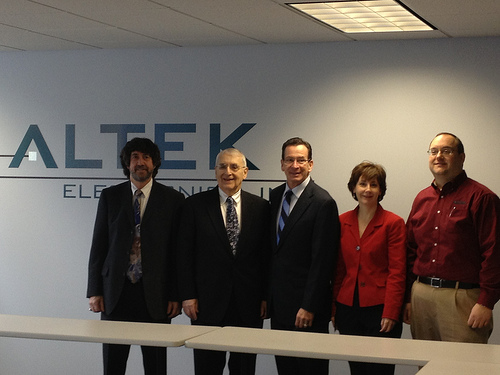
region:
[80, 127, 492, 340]
group of people posing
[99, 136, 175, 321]
man with a beard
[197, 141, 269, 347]
older man wearing glasses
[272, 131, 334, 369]
man wearing blue striped tie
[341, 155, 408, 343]
woman in red jacket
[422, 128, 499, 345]
man in burgundy shirt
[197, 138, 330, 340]
two men wearing glasses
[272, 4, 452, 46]
ceiling light panel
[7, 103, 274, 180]
word altek in blue letters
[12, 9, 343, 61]
panel pieces of ceiling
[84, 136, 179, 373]
man wearing suit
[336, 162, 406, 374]
woman wearing red jacket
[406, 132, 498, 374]
man wearing red shirt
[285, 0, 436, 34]
flourescent light on ceiling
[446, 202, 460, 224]
pen in shirt pocket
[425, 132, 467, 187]
man wearing glasses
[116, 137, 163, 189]
man with a beard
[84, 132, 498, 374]
five people standing in a room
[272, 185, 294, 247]
blue striped tie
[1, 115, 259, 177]
company logo on back of wall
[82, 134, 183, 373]
The man is standing.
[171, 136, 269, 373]
The man is standing.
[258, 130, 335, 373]
The man is standing.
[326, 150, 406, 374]
The woman is standing.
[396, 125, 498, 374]
The man is standing.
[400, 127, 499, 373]
The man is smiling.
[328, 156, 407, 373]
The woman is smiling.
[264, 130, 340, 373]
The man is smiling.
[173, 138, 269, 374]
The man is smiling.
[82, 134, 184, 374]
The man is smiling.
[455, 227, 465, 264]
MAN WEARING BURGANDY SHIRT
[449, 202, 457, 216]
INK PEN IN POCKET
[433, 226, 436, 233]
WHITE BUTTONS ON SHIRT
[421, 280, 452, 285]
MAN HAS ON A BELT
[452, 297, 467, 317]
MAN WEARING TAN PANTS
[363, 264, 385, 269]
LADY HAS ON A RED JACKET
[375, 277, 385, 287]
POCKET ON THE JACKET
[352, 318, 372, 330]
LADY WEARING BLACK PANTS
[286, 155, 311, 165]
MAN HAS ON EYE GLASSES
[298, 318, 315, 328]
MAN WEARING A RING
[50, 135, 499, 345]
people standing behind a white table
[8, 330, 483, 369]
a white table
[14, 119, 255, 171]
letters on the wall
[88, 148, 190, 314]
a man with dark hair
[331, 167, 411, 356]
a lady in a red shirt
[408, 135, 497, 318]
a man in a red shirt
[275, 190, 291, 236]
a blue striped tie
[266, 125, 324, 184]
a man wearing glasses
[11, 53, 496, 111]
a white wall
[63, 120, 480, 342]
people standing in a line